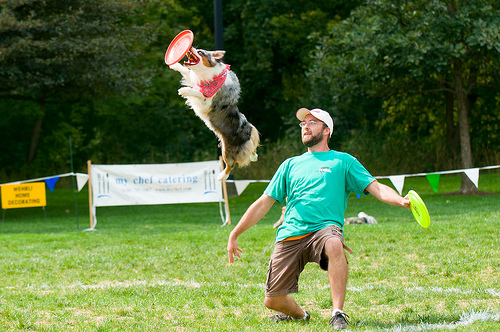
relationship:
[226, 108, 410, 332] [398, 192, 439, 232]
man playing frisbee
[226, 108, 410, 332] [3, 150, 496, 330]
man playing on field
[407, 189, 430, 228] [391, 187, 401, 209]
disk in hand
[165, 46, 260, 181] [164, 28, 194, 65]
dog catching frisbee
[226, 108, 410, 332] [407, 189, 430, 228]
man holding disk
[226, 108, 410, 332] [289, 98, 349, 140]
man wearing hat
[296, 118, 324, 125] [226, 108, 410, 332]
glasses of man man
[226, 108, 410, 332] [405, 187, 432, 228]
man holding frisbee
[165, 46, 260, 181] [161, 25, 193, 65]
dog to catch frisbee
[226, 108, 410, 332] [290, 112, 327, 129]
man wearing glasses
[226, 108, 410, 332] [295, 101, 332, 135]
man wearing cap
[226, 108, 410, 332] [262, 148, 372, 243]
man wearing shirt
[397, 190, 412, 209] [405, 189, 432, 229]
hand flying disk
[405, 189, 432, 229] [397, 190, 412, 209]
disk held by hand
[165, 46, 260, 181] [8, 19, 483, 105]
dog in air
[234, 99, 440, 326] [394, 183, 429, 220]
man holding frisbee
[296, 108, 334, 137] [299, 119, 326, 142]
cap on head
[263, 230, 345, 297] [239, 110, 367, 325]
shorts on man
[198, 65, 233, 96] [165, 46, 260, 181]
fabric wrapped around dog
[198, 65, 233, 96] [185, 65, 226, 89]
fabric wrapped around neck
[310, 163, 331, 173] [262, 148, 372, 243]
design on shirt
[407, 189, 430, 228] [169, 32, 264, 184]
disk caught by dog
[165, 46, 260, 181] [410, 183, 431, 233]
dog catches frisbee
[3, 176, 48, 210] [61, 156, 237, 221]
sign in middle of boundaries